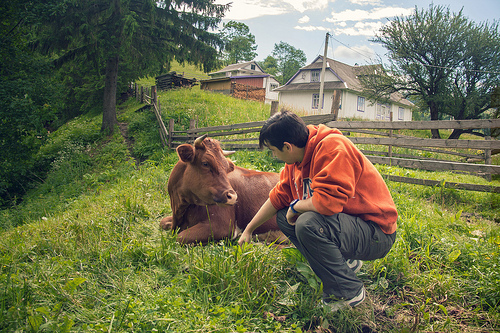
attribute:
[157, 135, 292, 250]
cow — brown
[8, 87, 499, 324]
ground — green, grassy, brown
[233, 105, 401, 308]
man — crouched, bending down, crouching, squatting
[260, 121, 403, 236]
sweatshirt — hooded, orange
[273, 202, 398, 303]
pants — grey, gray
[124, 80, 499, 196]
fence — wooden, long, slanted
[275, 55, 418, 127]
house — white, small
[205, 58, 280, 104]
house — white, small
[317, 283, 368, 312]
shoe — white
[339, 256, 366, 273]
shoe — white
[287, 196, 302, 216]
watch — black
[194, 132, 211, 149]
horn — small, pointy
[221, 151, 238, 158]
horn — pointy, small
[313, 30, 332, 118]
utility pole — tall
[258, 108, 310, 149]
hair — brown